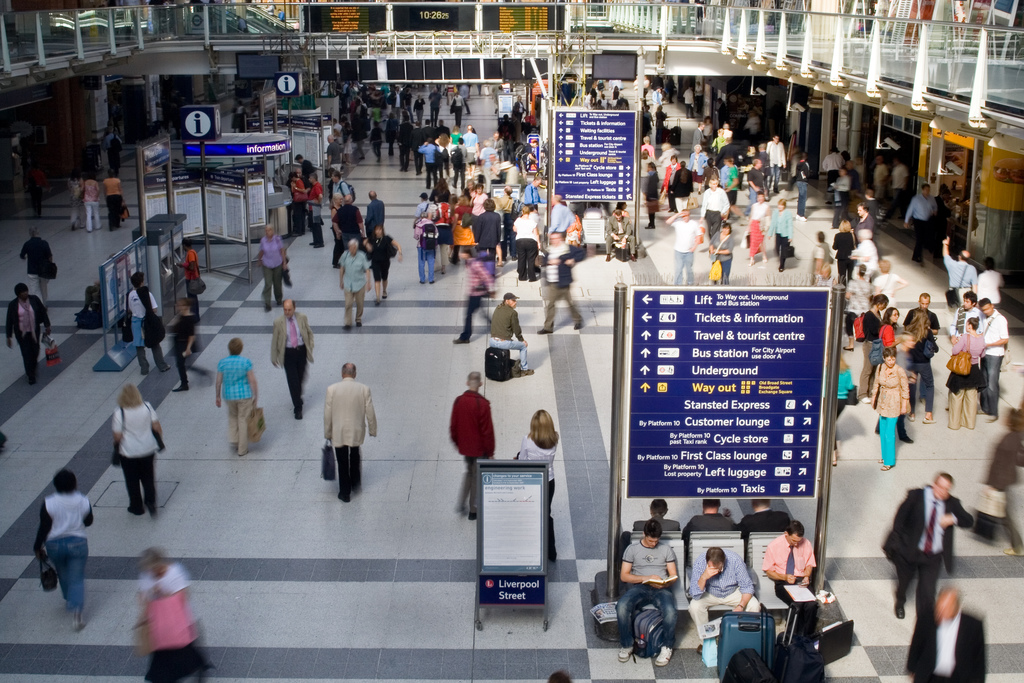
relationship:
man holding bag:
[306, 354, 387, 512] [306, 423, 345, 491]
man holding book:
[609, 512, 696, 675] [639, 572, 683, 598]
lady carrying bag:
[216, 337, 266, 456] [239, 398, 278, 450]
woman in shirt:
[36, 470, 95, 626] [44, 489, 96, 539]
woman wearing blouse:
[110, 382, 165, 515] [109, 403, 161, 455]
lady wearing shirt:
[221, 338, 267, 459] [221, 354, 260, 396]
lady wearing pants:
[221, 338, 267, 459] [223, 395, 256, 445]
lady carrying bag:
[216, 337, 266, 456] [245, 408, 269, 439]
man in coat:
[320, 363, 378, 504] [321, 381, 376, 449]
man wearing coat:
[452, 369, 502, 517] [449, 390, 496, 458]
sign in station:
[619, 287, 825, 497] [10, 4, 1015, 672]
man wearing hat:
[485, 291, 522, 363] [498, 291, 516, 305]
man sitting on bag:
[485, 292, 535, 382] [484, 347, 514, 383]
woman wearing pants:
[868, 340, 918, 474] [868, 419, 905, 471]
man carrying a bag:
[320, 363, 378, 504] [317, 441, 343, 481]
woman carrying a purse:
[940, 331, 993, 435] [938, 337, 977, 379]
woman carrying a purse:
[102, 387, 169, 521] [108, 398, 124, 463]